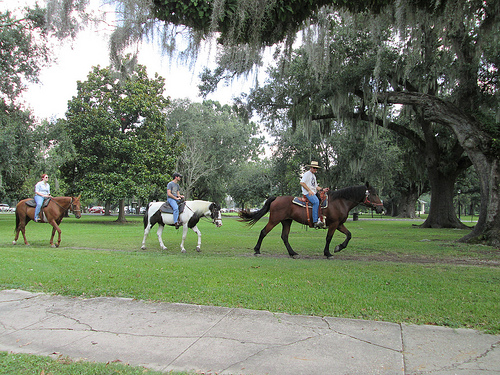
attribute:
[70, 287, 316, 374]
sidewalk — wide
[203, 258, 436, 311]
grass — green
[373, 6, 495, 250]
tree — large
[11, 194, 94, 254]
horse — brown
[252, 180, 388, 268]
horse — dark brown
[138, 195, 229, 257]
horse — white, black, small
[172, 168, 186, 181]
cap — black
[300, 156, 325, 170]
hat — white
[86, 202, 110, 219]
car — red, parked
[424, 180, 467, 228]
tree — thick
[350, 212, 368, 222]
can — brown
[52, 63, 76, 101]
cloud — white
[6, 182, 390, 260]
horses — walking